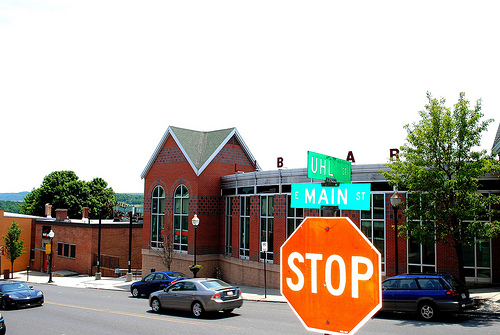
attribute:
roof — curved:
[216, 150, 423, 191]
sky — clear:
[1, 0, 498, 196]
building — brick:
[136, 118, 499, 301]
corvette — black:
[0, 278, 47, 311]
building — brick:
[135, 124, 279, 283]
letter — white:
[348, 253, 373, 299]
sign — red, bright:
[275, 215, 386, 333]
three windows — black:
[57, 242, 77, 258]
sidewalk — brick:
[37, 243, 207, 297]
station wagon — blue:
[380, 276, 467, 322]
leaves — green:
[378, 100, 498, 291]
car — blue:
[381, 274, 467, 321]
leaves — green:
[366, 81, 498, 278]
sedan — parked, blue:
[122, 265, 189, 302]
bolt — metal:
[321, 224, 331, 232]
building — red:
[31, 209, 139, 274]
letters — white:
[284, 247, 374, 303]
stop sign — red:
[267, 211, 388, 332]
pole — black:
[188, 222, 202, 275]